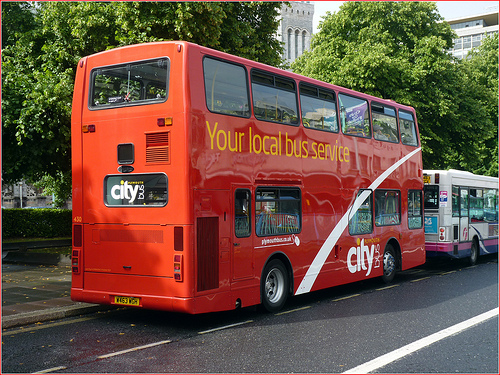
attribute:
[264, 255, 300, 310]
tire — black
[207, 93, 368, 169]
writing — shiny, white, yellow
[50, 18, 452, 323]
bus — red, white, yellow, double decker, regular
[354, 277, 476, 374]
line — white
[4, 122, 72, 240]
bush — green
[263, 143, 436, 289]
stripe — white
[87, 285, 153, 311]
plate — yellow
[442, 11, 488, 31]
hedgerow — green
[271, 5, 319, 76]
building — tall, large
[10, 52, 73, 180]
trees — bush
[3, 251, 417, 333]
sidewalk — gray